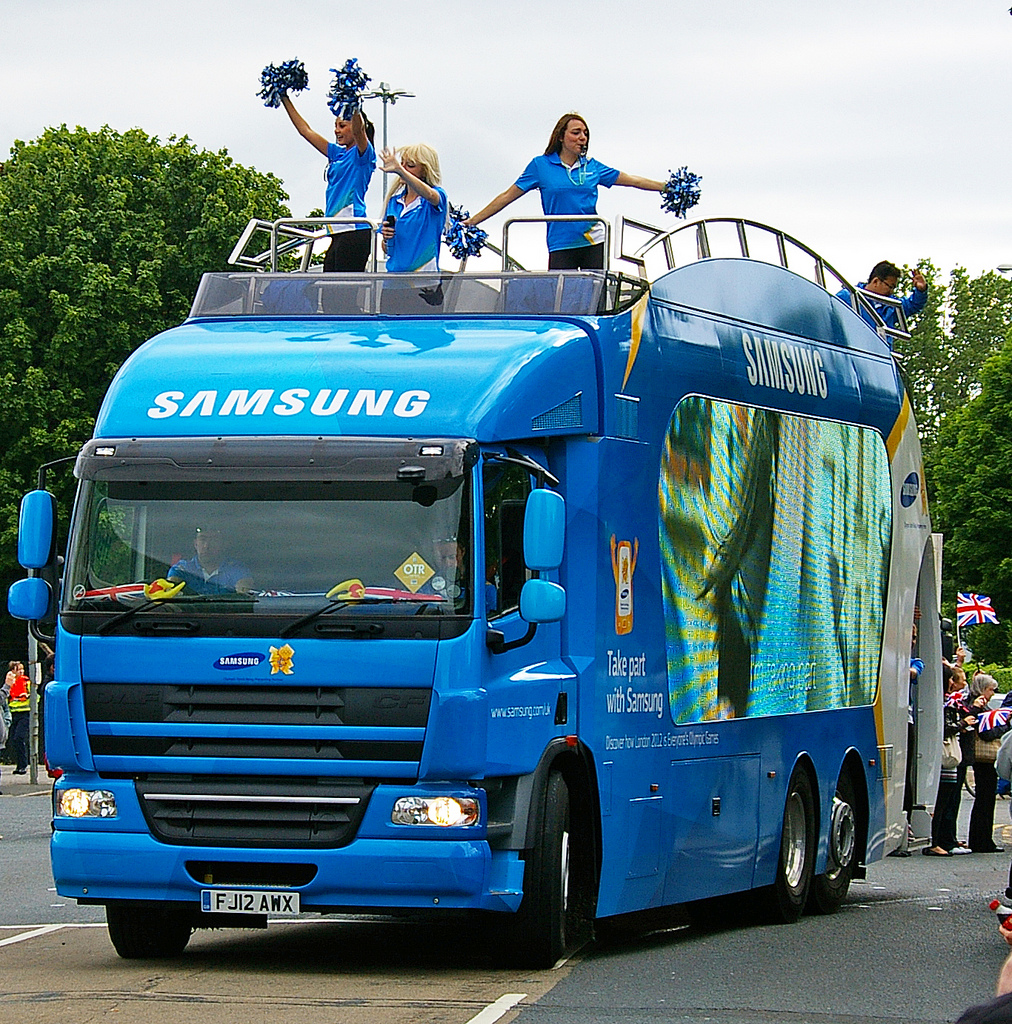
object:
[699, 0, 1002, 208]
sky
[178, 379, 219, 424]
letter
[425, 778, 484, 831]
headlights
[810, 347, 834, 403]
letter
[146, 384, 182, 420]
letter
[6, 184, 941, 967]
bus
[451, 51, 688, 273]
people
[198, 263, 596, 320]
roof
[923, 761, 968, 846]
pants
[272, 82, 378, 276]
woman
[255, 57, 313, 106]
pom-poms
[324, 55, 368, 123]
pom-poms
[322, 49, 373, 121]
pom-poms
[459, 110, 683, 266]
woman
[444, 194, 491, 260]
pom-poms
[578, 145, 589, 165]
wistle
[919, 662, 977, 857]
person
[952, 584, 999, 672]
flag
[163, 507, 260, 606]
passenger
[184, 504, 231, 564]
head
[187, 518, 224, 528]
sunglasses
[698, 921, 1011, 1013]
street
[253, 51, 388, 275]
person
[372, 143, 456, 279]
person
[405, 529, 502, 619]
man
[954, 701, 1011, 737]
flag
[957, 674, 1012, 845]
person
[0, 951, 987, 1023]
street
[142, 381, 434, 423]
lettering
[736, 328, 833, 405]
lettering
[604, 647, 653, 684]
lettering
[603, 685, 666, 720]
lettering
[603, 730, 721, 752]
lettering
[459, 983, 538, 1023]
line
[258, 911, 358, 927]
line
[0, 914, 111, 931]
line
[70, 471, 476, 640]
windshield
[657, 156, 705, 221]
pom-poms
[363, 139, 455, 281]
woman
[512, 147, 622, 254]
shirt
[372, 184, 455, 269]
shirt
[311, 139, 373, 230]
shirt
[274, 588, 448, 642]
windshield wipers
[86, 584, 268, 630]
windshield wipers